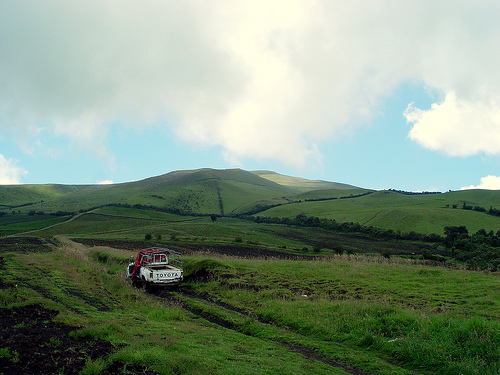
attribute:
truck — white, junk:
[126, 248, 185, 293]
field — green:
[2, 248, 500, 375]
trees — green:
[258, 214, 500, 271]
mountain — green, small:
[122, 168, 371, 223]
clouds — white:
[3, 0, 500, 161]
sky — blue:
[3, 0, 500, 194]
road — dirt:
[1, 208, 98, 236]